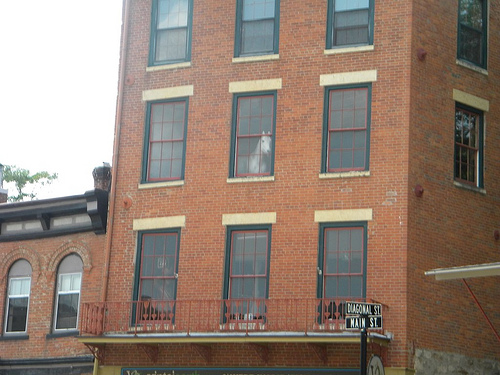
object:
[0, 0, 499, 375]
building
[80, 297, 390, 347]
balcony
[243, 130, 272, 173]
horse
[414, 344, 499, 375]
poster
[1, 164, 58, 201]
trees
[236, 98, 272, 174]
glass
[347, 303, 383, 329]
words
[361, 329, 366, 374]
pole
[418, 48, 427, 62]
siren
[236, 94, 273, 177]
bars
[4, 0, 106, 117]
sky